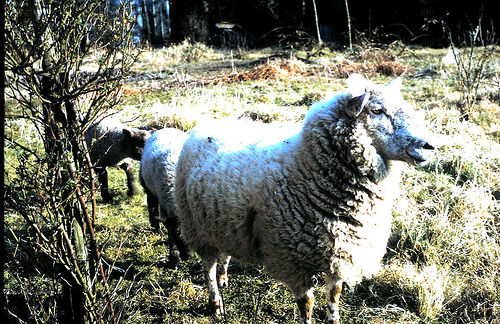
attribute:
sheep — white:
[132, 93, 454, 322]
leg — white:
[294, 287, 316, 321]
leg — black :
[163, 214, 188, 261]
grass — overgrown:
[358, 45, 496, 311]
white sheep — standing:
[181, 45, 198, 60]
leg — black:
[93, 166, 113, 201]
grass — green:
[399, 169, 498, 321]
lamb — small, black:
[74, 113, 152, 205]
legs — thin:
[206, 250, 228, 320]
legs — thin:
[296, 285, 346, 322]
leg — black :
[162, 215, 190, 271]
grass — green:
[392, 260, 459, 316]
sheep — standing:
[180, 37, 337, 244]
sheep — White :
[105, 79, 475, 226]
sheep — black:
[160, 102, 391, 209]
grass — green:
[370, 262, 493, 319]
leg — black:
[124, 160, 137, 191]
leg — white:
[199, 254, 225, 318]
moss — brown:
[201, 44, 416, 96]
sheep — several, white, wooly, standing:
[173, 75, 426, 319]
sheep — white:
[173, 71, 454, 321]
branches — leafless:
[36, 125, 130, 317]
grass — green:
[0, 47, 491, 317]